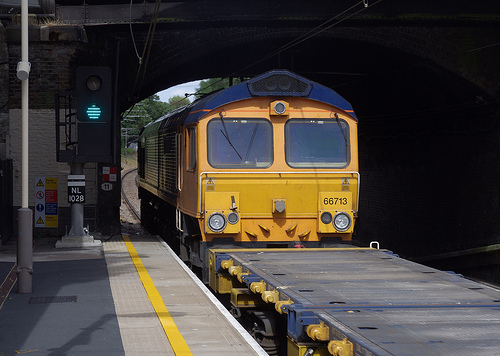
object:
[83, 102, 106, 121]
light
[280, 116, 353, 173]
window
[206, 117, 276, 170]
window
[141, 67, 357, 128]
top of train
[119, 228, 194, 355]
line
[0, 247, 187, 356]
shadow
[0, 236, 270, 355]
floor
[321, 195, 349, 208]
numbers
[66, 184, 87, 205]
letters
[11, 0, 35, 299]
post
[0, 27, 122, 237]
wall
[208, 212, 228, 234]
headlight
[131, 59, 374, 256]
train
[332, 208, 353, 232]
headlight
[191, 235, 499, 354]
flat bed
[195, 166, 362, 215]
handle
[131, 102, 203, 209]
side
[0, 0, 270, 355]
platform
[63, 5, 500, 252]
tunnel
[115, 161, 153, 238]
train tracks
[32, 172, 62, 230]
warning sign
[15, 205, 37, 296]
concrete base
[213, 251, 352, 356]
bolts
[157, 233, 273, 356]
edge